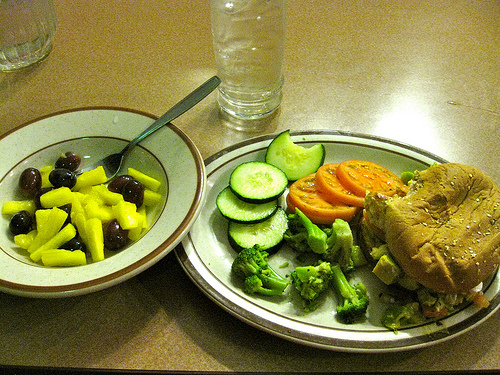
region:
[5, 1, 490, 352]
Fruit and vegetable meal with water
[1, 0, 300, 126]
Two glasses of water on the table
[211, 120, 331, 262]
Four cucumber slices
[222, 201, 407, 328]
Pieces of broccoli on a plate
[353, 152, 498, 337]
hamburger with a bite taken out of it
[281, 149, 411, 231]
Slices of tomato stacked on each other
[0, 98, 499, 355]
White plates with brown rims with food on them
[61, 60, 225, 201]
Metal spoon in fruit salad bowl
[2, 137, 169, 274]
Grapes and small pineapple chunks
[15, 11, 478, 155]
Creamy-brown colored table top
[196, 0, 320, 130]
a glass with water and ice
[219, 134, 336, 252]
sliced cucumbers on a plate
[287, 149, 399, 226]
sliced tomatoes on a plate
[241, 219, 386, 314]
broccoli on a plate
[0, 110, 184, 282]
a bowl of grapes and pineapple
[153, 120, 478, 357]
a plate of food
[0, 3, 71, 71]
a clear water jug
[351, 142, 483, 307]
a sandwich with a bite taken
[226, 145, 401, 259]
sliced vegetables on a plate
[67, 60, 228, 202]
a fork in a bowl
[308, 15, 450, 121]
this is a table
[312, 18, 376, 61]
the table is brown in color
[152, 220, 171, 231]
the plate is white in color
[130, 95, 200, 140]
this is a fox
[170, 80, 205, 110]
the fox is metallic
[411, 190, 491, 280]
this is a snack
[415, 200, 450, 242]
the snack is brown in color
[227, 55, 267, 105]
this is a glass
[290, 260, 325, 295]
this is a brow coli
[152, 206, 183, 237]
this is a plate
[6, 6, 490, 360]
a healthy and complete meal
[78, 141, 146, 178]
silver fork in a bowl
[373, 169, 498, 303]
a burger with a bite out of it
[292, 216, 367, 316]
cut up pieces of broccoli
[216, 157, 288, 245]
sliced cucumber pieces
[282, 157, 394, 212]
sliced red tomatoes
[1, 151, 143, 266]
a mix of cut pineapple and red grapes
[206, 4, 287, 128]
a glass of ice water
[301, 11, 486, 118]
shiny brown table top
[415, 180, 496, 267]
smashed sesame seed bun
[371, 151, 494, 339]
a sandwich on a plate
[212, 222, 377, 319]
green broccoli on a plate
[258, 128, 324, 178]
a sliced cucumber with a bite taken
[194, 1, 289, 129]
a water glass with ice and water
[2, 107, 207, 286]
grapes and sliced pineapples